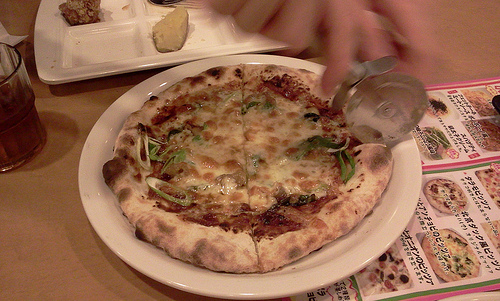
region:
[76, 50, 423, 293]
a pizza on a white plate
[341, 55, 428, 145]
a silver pizza cutter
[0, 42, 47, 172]
a lie on the table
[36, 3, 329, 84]
a white tray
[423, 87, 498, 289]
a menu on the table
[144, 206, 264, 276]
the crust of the pizza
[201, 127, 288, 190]
the cheese on the pizza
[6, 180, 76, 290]
the table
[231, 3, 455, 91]
a hand of the person cutting the pizza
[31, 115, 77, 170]
the shadow of the cup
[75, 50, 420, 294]
A small personal pizza on a plate.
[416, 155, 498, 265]
A menu showing the different pizzas available.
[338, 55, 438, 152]
A pizza cutter slicing the pizza.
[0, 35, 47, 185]
A glass with a brown liquid in it.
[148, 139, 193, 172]
A small green vegetable on the pizza.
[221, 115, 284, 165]
Melted white cheese on the pizza.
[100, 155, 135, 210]
The slightly burn crust of the pizza.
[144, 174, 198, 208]
A large, oval shaped green vegetable on the pizza.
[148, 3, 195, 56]
A partially eaten piece of food on a plate.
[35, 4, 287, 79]
A serving tray with several compartments.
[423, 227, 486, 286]
picture of pizza on menu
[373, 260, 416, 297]
picture of pizza on menu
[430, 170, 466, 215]
picture of pizza on menu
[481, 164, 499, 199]
picture of pizza on menu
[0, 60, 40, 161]
cup is half full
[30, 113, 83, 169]
shadow of cup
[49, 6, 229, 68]
plate with square pallets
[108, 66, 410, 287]
pizza on white plate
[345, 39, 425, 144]
pizza cutter is cutting pizza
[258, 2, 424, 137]
hand holding pizza cutter